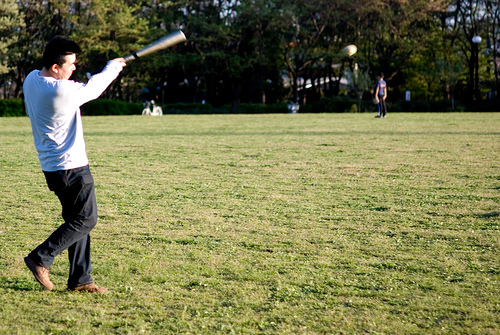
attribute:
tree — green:
[226, 0, 298, 113]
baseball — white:
[339, 42, 359, 59]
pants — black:
[31, 170, 124, 281]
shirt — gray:
[19, 55, 144, 179]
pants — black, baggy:
[27, 165, 97, 289]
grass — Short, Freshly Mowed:
[135, 124, 459, 318]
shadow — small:
[467, 208, 497, 220]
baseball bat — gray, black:
[121, 31, 187, 67]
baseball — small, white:
[344, 42, 359, 55]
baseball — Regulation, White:
[303, 26, 366, 79]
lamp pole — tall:
[459, 27, 495, 110]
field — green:
[2, 110, 499, 333]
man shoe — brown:
[25, 39, 111, 288]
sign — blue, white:
[401, 86, 415, 94]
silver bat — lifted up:
[123, 30, 185, 65]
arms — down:
[374, 84, 389, 102]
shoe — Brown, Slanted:
[15, 245, 75, 302]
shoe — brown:
[65, 278, 113, 300]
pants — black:
[24, 161, 96, 282]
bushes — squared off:
[1, 81, 496, 112]